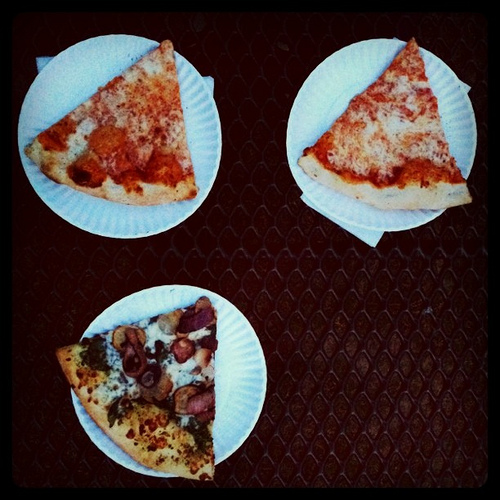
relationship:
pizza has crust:
[38, 60, 199, 213] [42, 165, 185, 207]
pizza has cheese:
[38, 60, 199, 213] [110, 90, 147, 143]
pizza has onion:
[64, 296, 231, 480] [147, 317, 183, 329]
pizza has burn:
[38, 60, 199, 213] [73, 159, 106, 197]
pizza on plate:
[38, 60, 199, 213] [15, 43, 233, 244]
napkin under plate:
[203, 79, 219, 95] [15, 43, 233, 244]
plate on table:
[15, 43, 233, 244] [17, 12, 479, 494]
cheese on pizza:
[110, 90, 147, 143] [38, 60, 199, 213]